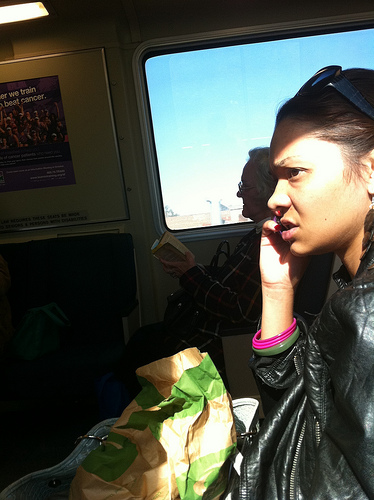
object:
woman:
[124, 61, 374, 500]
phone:
[256, 188, 297, 251]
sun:
[155, 88, 246, 173]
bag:
[70, 328, 237, 499]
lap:
[99, 361, 257, 499]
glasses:
[281, 58, 367, 118]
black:
[321, 385, 366, 481]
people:
[158, 57, 374, 457]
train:
[7, 1, 369, 499]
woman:
[111, 149, 274, 387]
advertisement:
[0, 67, 76, 192]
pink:
[266, 340, 275, 345]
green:
[275, 349, 283, 354]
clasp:
[69, 432, 105, 451]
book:
[131, 228, 212, 279]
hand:
[230, 215, 310, 290]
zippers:
[280, 419, 304, 486]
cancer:
[17, 93, 44, 104]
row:
[1, 206, 94, 252]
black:
[1, 204, 88, 233]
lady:
[234, 64, 374, 499]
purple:
[290, 329, 295, 333]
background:
[3, 9, 373, 204]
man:
[122, 144, 277, 395]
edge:
[122, 25, 174, 239]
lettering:
[1, 209, 94, 231]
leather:
[208, 235, 232, 267]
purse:
[158, 236, 231, 318]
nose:
[265, 180, 296, 212]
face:
[251, 99, 358, 260]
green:
[180, 370, 217, 406]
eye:
[287, 162, 315, 181]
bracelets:
[245, 317, 302, 351]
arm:
[224, 274, 309, 404]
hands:
[164, 260, 185, 277]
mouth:
[264, 212, 311, 240]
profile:
[235, 148, 277, 223]